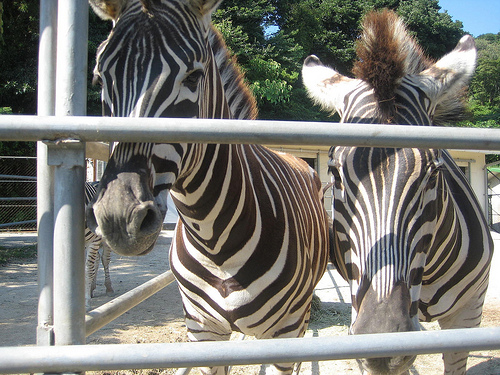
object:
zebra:
[301, 8, 494, 374]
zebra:
[83, 182, 116, 297]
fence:
[0, 1, 500, 374]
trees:
[1, 0, 500, 130]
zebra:
[87, 0, 327, 375]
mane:
[352, 8, 417, 118]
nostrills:
[85, 204, 156, 238]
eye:
[94, 72, 106, 87]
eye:
[428, 163, 442, 181]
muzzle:
[352, 225, 412, 374]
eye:
[329, 162, 345, 187]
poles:
[1, 2, 499, 374]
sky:
[0, 0, 499, 35]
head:
[301, 9, 476, 375]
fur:
[306, 5, 495, 375]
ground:
[0, 181, 500, 364]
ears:
[413, 33, 478, 103]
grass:
[0, 234, 48, 268]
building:
[77, 135, 491, 227]